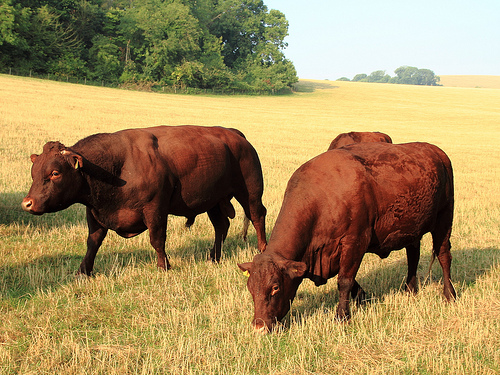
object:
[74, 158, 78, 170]
tag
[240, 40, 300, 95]
tree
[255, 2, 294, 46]
tree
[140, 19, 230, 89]
tree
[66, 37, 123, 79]
tree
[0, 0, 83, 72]
tree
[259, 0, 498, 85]
sky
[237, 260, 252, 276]
ear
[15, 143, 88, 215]
head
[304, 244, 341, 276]
brisket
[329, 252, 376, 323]
front legs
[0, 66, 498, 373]
grass field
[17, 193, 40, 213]
nose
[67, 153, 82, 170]
cow ear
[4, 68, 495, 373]
field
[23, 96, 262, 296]
cow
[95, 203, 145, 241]
brisket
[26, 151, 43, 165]
ear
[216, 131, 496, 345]
cow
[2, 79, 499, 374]
golden grass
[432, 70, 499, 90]
hill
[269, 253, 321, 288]
ear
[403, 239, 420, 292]
leg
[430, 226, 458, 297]
leg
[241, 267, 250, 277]
tag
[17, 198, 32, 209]
nostrils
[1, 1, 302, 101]
trees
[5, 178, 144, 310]
left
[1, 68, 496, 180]
background